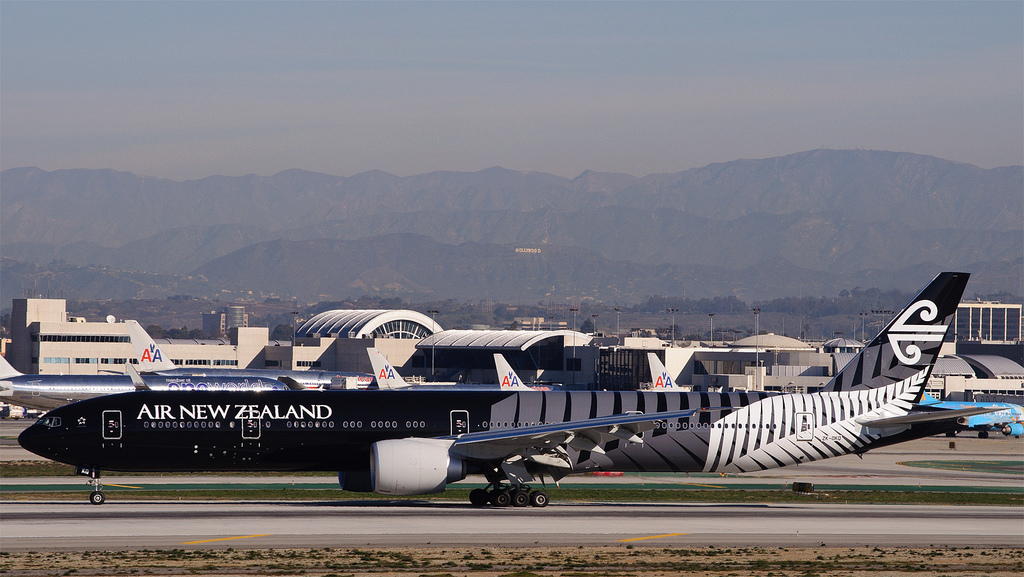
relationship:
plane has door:
[10, 262, 1020, 518] [89, 400, 124, 461]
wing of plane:
[439, 394, 718, 479] [2, 257, 988, 499]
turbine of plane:
[336, 413, 520, 496] [10, 262, 1020, 518]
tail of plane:
[817, 253, 980, 374] [10, 262, 1020, 518]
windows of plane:
[137, 398, 433, 435] [10, 262, 1020, 518]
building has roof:
[289, 302, 449, 376] [303, 298, 437, 331]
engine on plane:
[359, 417, 470, 502] [2, 257, 988, 499]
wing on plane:
[452, 409, 698, 449] [2, 257, 988, 499]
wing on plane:
[452, 409, 698, 449] [10, 262, 1020, 518]